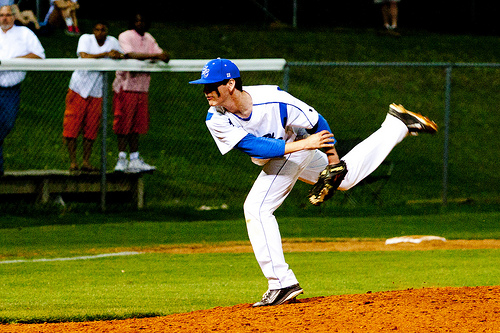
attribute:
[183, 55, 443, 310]
pitcher — male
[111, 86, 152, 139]
shorts — red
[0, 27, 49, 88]
shirt — white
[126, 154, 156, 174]
shoe — white, tennis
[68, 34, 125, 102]
shirt — white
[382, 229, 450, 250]
base — third, covered, white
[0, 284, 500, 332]
mound — pitcher's, clumpy, large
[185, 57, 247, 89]
cap — blue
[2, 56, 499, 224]
fence — chain link, green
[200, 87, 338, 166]
shirt — white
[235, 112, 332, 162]
undershirt — blue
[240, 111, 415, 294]
pants — white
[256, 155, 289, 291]
stripe — blue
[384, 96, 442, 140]
shoe — black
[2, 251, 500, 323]
grass — green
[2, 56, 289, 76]
padding — white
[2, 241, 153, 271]
line — white